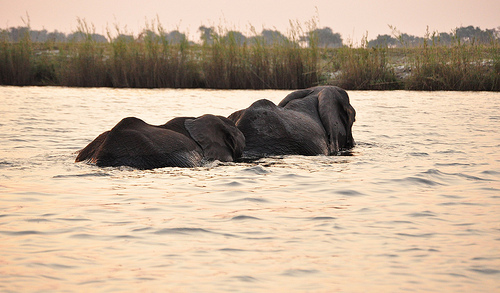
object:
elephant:
[75, 114, 246, 170]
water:
[0, 86, 499, 293]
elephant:
[227, 85, 356, 160]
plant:
[107, 31, 142, 89]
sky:
[0, 0, 499, 50]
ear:
[184, 113, 237, 161]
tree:
[198, 25, 220, 50]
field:
[0, 47, 499, 91]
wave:
[334, 189, 371, 197]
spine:
[94, 115, 197, 164]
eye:
[243, 146, 246, 151]